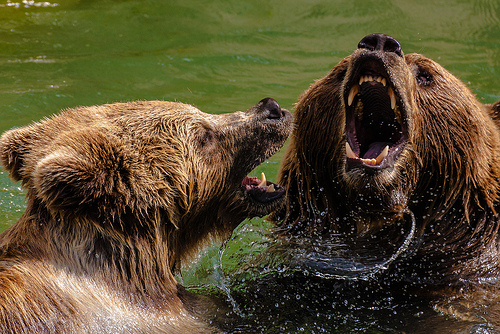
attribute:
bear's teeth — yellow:
[339, 70, 408, 124]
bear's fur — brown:
[23, 135, 208, 309]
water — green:
[19, 19, 346, 120]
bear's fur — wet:
[68, 146, 198, 307]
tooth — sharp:
[338, 86, 365, 120]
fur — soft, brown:
[121, 128, 199, 226]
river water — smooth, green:
[28, 4, 271, 104]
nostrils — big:
[374, 28, 401, 58]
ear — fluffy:
[31, 143, 110, 206]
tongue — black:
[361, 128, 389, 165]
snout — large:
[219, 99, 290, 151]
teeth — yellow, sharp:
[340, 145, 391, 170]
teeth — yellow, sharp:
[342, 74, 401, 111]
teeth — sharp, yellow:
[255, 174, 281, 201]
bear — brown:
[0, 97, 300, 332]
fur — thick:
[58, 176, 158, 326]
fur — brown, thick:
[429, 137, 484, 222]